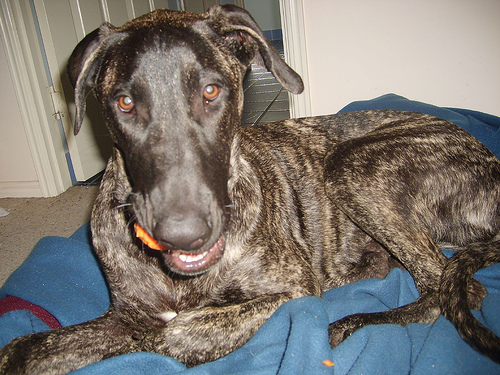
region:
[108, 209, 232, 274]
Dog with the ball in his mouth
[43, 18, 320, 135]
dog with large floppy ears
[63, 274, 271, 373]
dog laying on its paws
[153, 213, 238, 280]
dog with its mouth open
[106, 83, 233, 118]
dog with brown eyes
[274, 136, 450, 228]
dog with brown and black fur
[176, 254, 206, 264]
dog showing his teeth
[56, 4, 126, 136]
dog with black floppy ears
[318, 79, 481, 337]
dog laying a blue blanket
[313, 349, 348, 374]
crumbs on the bread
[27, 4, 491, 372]
dog sitting on blanket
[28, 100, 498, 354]
blue blanket under dog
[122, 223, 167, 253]
orange object in dogs mouth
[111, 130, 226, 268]
black snout of dog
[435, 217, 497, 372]
black curly tail of dog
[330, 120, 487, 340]
bag leg of dog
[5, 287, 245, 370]
leg of dog on blanket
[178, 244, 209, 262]
white teeth of dog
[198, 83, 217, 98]
brown eye of dog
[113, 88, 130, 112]
brown eye of dog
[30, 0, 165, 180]
open white door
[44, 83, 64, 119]
white painted door hinge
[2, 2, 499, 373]
black and blonde dog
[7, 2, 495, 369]
dog laying on blue blanket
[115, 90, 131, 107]
left eye of dog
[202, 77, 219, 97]
right eye of dog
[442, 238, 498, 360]
tail of a dog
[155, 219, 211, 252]
brown dog's nose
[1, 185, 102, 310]
off white carpet on floor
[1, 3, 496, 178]
wall painted the color white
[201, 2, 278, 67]
right ear on dog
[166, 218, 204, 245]
dog nose is black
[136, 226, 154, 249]
food in dogs mouth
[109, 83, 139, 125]
left eye on dog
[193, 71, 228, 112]
right eye on dog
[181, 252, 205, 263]
teeth in dog mouth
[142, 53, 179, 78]
middle of dog forehead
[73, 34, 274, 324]
face of the dog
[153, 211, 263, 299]
mouth of he dog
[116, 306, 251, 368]
front legs folded by dog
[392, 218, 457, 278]
back legs of the dog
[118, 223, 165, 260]
tongue of the dog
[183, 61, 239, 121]
eye of the dog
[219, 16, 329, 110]
ear of the dog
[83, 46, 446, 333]
a dog sitting in cloth